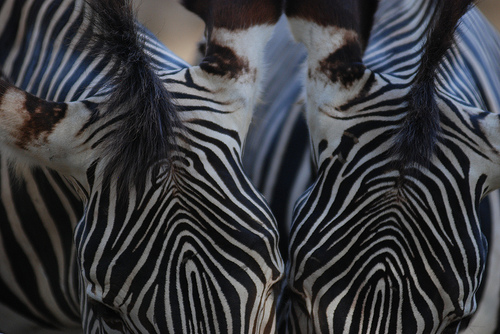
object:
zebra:
[0, 0, 283, 333]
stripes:
[334, 174, 452, 318]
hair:
[59, 0, 189, 196]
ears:
[178, 0, 284, 105]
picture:
[0, 0, 499, 334]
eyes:
[81, 288, 129, 330]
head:
[0, 0, 282, 334]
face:
[75, 81, 285, 334]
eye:
[264, 271, 289, 301]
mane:
[396, 0, 474, 177]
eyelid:
[83, 286, 120, 307]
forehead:
[130, 160, 228, 255]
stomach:
[228, 49, 325, 210]